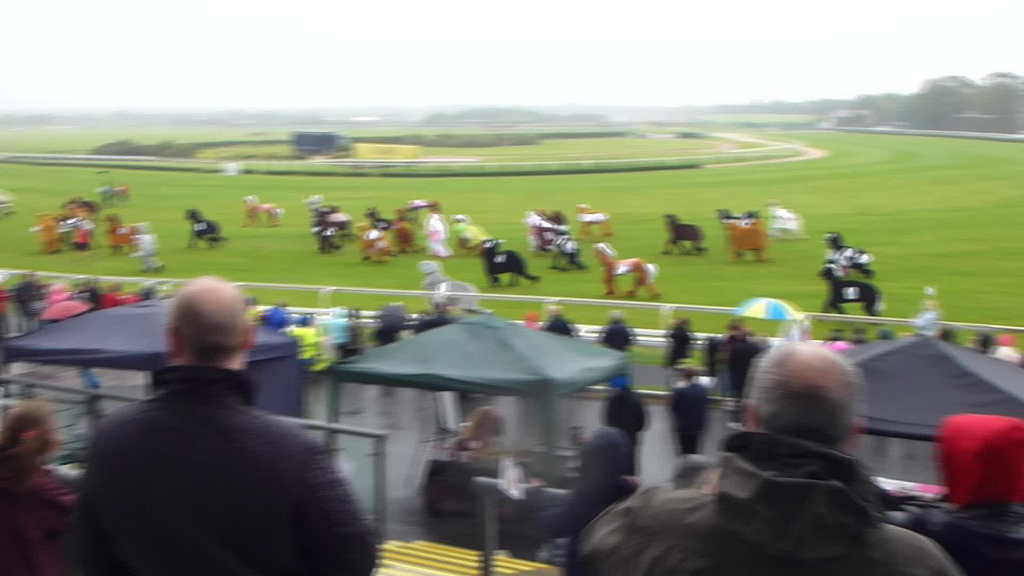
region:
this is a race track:
[90, 142, 1020, 501]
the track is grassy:
[576, 162, 804, 293]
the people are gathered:
[134, 262, 730, 510]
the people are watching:
[90, 250, 871, 486]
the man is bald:
[117, 256, 286, 381]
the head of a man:
[155, 271, 289, 376]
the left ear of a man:
[155, 318, 198, 358]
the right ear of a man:
[225, 320, 280, 352]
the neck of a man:
[172, 344, 230, 382]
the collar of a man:
[152, 356, 254, 414]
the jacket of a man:
[96, 385, 347, 554]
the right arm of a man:
[254, 417, 411, 572]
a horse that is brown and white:
[576, 224, 669, 297]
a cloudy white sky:
[5, 0, 1020, 125]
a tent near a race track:
[321, 312, 625, 548]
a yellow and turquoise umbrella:
[730, 299, 806, 322]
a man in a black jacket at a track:
[69, 279, 376, 573]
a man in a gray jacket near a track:
[564, 344, 969, 572]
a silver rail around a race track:
[3, 264, 1019, 353]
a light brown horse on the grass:
[590, 242, 664, 304]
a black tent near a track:
[827, 337, 1021, 496]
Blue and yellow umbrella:
[735, 294, 805, 337]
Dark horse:
[655, 206, 713, 258]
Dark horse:
[819, 259, 887, 313]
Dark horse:
[475, 237, 548, 289]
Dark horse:
[179, 200, 227, 243]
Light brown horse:
[589, 241, 665, 300]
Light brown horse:
[238, 193, 289, 228]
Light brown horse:
[354, 218, 397, 261]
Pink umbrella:
[32, 296, 91, 325]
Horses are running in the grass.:
[49, 181, 907, 317]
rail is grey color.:
[267, 390, 416, 545]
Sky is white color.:
[30, 28, 866, 83]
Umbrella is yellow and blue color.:
[729, 283, 815, 325]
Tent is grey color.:
[54, 261, 981, 442]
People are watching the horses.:
[30, 286, 969, 559]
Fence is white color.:
[26, 261, 997, 392]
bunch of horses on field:
[17, 184, 906, 317]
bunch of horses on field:
[10, 168, 908, 309]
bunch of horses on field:
[19, 170, 912, 322]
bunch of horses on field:
[16, 173, 899, 304]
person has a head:
[172, 280, 256, 367]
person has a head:
[745, 337, 872, 454]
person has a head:
[938, 410, 1021, 500]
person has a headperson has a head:
[608, 305, 625, 319]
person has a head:
[542, 298, 563, 314]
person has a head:
[728, 314, 741, 333]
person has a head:
[608, 315, 621, 326]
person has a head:
[20, 270, 33, 284]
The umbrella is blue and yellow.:
[730, 291, 811, 342]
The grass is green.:
[448, 159, 1022, 286]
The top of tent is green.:
[384, 306, 635, 405]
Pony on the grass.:
[578, 233, 684, 292]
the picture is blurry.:
[54, 240, 979, 560]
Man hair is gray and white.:
[746, 341, 860, 443]